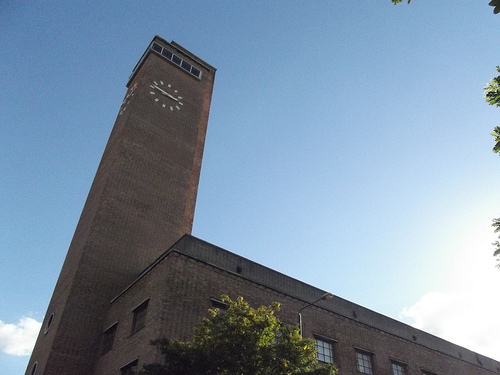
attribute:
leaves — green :
[231, 304, 309, 364]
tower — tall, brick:
[75, 32, 218, 234]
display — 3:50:
[147, 78, 186, 114]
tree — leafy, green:
[144, 292, 339, 375]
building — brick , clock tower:
[100, 235, 500, 374]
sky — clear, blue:
[218, 1, 487, 246]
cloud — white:
[1, 317, 35, 359]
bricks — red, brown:
[161, 262, 202, 334]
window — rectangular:
[153, 44, 205, 81]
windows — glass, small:
[132, 299, 148, 333]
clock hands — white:
[152, 81, 180, 103]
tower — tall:
[26, 36, 217, 374]